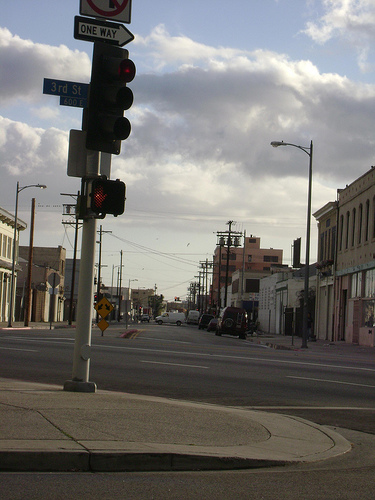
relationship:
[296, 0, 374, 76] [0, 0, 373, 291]
white cloud in sky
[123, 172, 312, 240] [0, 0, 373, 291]
white cloud in sky